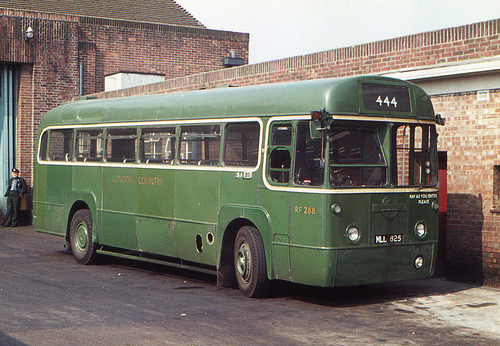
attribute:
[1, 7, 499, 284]
building — bricks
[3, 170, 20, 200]
shirt — blue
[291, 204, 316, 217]
word — orange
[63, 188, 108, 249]
tire — black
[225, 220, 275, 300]
tire — round, inflated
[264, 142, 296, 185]
window — open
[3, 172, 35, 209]
jacket — black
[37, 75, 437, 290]
bus — green 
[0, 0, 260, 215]
building — bricked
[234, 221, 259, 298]
tire — round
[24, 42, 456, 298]
bus — green 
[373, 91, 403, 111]
numbers — white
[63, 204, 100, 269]
tire — inflated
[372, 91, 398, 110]
numbers — white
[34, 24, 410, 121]
bricks — red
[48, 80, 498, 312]
wall — brick